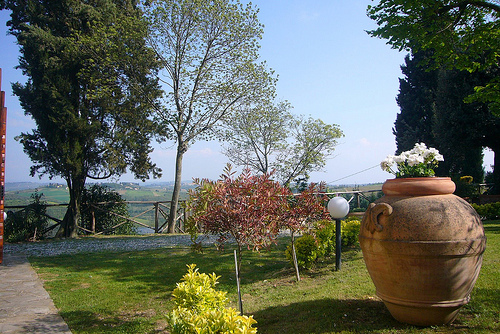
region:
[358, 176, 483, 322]
A big earthen planter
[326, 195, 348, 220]
A white garden nlight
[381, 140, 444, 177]
A plant with white flowers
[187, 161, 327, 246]
Red leaves on two trees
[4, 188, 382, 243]
A wooden fence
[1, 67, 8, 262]
A amall part of a wall visible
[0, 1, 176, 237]
One of the big green trees in the garden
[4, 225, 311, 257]
A short wall under the wooden fence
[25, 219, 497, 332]
Lawn in the garden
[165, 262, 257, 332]
A small bush with yellow leaves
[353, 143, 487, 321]
Large pot planter in the forefront.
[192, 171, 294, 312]
Small red tree by planter.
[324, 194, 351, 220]
White garden globe on pole.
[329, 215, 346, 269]
Black pole holding garden globe.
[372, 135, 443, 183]
white flowers in the planter.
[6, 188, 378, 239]
Wooden fence in the background.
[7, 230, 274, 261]
Gravel on the ground.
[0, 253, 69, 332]
Paved cement on the ground.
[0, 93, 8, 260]
Brick on the building.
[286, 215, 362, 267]
Green bushes by the planter.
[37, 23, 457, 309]
an overlook at a park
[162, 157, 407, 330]
the trees are small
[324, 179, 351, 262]
a small lantern light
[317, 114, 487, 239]
the flowers are white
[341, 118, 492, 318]
the flowers are in a vase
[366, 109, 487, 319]
the vase is stone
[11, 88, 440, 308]
the fencing is wooden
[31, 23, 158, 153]
leaves on this tree are green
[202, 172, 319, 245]
leaves on this tree are red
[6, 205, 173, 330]
a pathway through the garden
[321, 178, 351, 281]
a light is staked into the ground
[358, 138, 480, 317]
a big planter has some flowers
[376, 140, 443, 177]
the flowers in the planter are white ones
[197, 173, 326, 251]
some small trees grow to the left of the planter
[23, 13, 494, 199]
larger trees can be seen in the background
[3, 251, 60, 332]
a portion of a pathway can be seen to the left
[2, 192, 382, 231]
a wood fence is on the other side of the gravel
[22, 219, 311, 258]
a gravel pathway is in the background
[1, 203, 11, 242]
another light is in the background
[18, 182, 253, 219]
some homes on a hill can be seen in the distance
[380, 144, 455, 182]
potted flowers in the vase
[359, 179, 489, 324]
a large vase for landscaping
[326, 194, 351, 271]
the globe in the yard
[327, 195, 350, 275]
the globe behind the vase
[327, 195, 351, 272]
the globe by the little trees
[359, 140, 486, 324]
flowers in a large vase for the yard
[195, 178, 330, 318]
two young red leafe trees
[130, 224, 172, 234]
water off in the distant background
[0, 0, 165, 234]
tree full of leaves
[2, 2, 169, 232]
the tree on the left